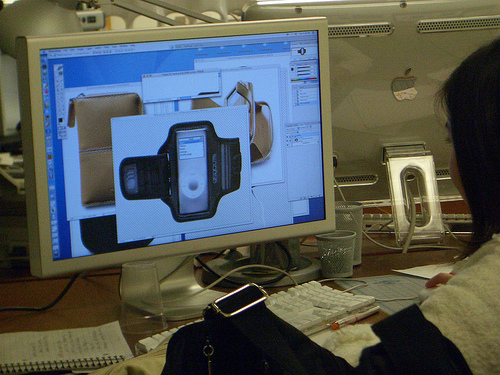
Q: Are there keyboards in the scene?
A: Yes, there is a keyboard.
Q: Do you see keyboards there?
A: Yes, there is a keyboard.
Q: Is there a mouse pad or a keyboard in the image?
A: Yes, there is a keyboard.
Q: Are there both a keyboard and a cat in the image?
A: No, there is a keyboard but no cats.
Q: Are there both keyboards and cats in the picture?
A: No, there is a keyboard but no cats.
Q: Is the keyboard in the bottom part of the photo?
A: Yes, the keyboard is in the bottom of the image.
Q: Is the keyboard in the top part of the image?
A: No, the keyboard is in the bottom of the image.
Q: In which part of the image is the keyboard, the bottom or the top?
A: The keyboard is in the bottom of the image.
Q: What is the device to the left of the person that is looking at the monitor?
A: The device is a keyboard.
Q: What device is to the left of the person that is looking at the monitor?
A: The device is a keyboard.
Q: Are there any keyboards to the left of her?
A: Yes, there is a keyboard to the left of the lady.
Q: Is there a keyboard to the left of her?
A: Yes, there is a keyboard to the left of the lady.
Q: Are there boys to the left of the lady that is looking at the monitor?
A: No, there is a keyboard to the left of the lady.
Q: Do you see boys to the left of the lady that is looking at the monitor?
A: No, there is a keyboard to the left of the lady.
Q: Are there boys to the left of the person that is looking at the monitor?
A: No, there is a keyboard to the left of the lady.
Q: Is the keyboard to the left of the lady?
A: Yes, the keyboard is to the left of the lady.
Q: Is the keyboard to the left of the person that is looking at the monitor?
A: Yes, the keyboard is to the left of the lady.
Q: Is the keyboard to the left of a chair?
A: No, the keyboard is to the left of the lady.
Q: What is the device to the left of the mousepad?
A: The device is a keyboard.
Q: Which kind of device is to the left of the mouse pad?
A: The device is a keyboard.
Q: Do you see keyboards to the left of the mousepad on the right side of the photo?
A: Yes, there is a keyboard to the left of the mousepad.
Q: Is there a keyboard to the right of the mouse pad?
A: No, the keyboard is to the left of the mouse pad.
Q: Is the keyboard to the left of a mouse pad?
A: Yes, the keyboard is to the left of a mouse pad.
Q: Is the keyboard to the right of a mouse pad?
A: No, the keyboard is to the left of a mouse pad.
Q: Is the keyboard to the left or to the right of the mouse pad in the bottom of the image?
A: The keyboard is to the left of the mousepad.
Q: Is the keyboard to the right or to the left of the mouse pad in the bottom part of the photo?
A: The keyboard is to the left of the mousepad.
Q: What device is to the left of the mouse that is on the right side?
A: The device is a keyboard.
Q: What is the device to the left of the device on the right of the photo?
A: The device is a keyboard.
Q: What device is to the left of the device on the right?
A: The device is a keyboard.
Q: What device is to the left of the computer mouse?
A: The device is a keyboard.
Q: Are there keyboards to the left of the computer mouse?
A: Yes, there is a keyboard to the left of the computer mouse.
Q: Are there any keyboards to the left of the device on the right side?
A: Yes, there is a keyboard to the left of the computer mouse.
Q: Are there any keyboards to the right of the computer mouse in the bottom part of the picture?
A: No, the keyboard is to the left of the computer mouse.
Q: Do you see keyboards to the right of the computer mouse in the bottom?
A: No, the keyboard is to the left of the computer mouse.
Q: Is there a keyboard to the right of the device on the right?
A: No, the keyboard is to the left of the computer mouse.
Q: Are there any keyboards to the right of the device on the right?
A: No, the keyboard is to the left of the computer mouse.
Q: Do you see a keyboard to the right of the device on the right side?
A: No, the keyboard is to the left of the computer mouse.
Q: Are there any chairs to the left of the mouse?
A: No, there is a keyboard to the left of the mouse.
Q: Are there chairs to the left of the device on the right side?
A: No, there is a keyboard to the left of the mouse.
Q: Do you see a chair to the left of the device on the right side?
A: No, there is a keyboard to the left of the mouse.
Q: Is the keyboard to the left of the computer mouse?
A: Yes, the keyboard is to the left of the computer mouse.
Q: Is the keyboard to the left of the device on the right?
A: Yes, the keyboard is to the left of the computer mouse.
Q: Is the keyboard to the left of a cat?
A: No, the keyboard is to the left of the computer mouse.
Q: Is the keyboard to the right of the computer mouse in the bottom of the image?
A: No, the keyboard is to the left of the mouse.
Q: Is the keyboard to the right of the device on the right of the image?
A: No, the keyboard is to the left of the mouse.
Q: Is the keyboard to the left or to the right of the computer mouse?
A: The keyboard is to the left of the computer mouse.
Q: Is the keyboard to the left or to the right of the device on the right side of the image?
A: The keyboard is to the left of the computer mouse.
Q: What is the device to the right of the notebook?
A: The device is a keyboard.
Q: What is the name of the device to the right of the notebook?
A: The device is a keyboard.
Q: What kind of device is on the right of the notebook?
A: The device is a keyboard.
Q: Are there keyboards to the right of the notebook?
A: Yes, there is a keyboard to the right of the notebook.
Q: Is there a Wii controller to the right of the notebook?
A: No, there is a keyboard to the right of the notebook.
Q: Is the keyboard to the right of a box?
A: No, the keyboard is to the right of the notebook.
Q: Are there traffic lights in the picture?
A: No, there are no traffic lights.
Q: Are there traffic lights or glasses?
A: No, there are no traffic lights or glasses.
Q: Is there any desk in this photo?
A: Yes, there is a desk.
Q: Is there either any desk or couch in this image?
A: Yes, there is a desk.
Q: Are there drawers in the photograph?
A: No, there are no drawers.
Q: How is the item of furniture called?
A: The piece of furniture is a desk.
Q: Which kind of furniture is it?
A: The piece of furniture is a desk.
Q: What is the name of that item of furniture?
A: This is a desk.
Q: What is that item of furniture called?
A: This is a desk.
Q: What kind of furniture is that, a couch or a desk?
A: This is a desk.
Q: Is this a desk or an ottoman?
A: This is a desk.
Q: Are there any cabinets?
A: No, there are no cabinets.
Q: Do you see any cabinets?
A: No, there are no cabinets.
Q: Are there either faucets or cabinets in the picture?
A: No, there are no cabinets or faucets.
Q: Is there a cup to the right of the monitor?
A: Yes, there are cups to the right of the monitor.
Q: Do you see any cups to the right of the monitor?
A: Yes, there are cups to the right of the monitor.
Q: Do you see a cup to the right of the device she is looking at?
A: Yes, there are cups to the right of the monitor.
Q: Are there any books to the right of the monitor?
A: No, there are cups to the right of the monitor.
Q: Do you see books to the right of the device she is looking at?
A: No, there are cups to the right of the monitor.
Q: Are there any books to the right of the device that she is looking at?
A: No, there are cups to the right of the monitor.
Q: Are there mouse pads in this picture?
A: Yes, there is a mouse pad.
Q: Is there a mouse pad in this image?
A: Yes, there is a mouse pad.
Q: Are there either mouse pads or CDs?
A: Yes, there is a mouse pad.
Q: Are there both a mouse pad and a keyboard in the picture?
A: Yes, there are both a mouse pad and a keyboard.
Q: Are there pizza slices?
A: No, there are no pizza slices.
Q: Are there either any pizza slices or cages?
A: No, there are no pizza slices or cages.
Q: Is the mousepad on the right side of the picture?
A: Yes, the mousepad is on the right of the image.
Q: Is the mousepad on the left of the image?
A: No, the mousepad is on the right of the image.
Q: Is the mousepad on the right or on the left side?
A: The mousepad is on the right of the image.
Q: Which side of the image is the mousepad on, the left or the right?
A: The mousepad is on the right of the image.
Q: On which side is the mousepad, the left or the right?
A: The mousepad is on the right of the image.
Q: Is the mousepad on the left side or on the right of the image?
A: The mousepad is on the right of the image.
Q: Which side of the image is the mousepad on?
A: The mousepad is on the right of the image.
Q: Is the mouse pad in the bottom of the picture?
A: Yes, the mouse pad is in the bottom of the image.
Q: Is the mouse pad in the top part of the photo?
A: No, the mouse pad is in the bottom of the image.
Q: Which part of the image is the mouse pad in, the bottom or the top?
A: The mouse pad is in the bottom of the image.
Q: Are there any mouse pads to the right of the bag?
A: Yes, there is a mouse pad to the right of the bag.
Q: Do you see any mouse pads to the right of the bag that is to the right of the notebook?
A: Yes, there is a mouse pad to the right of the bag.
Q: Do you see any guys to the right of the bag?
A: No, there is a mouse pad to the right of the bag.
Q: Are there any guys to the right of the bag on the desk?
A: No, there is a mouse pad to the right of the bag.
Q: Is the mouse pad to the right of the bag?
A: Yes, the mouse pad is to the right of the bag.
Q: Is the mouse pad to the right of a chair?
A: No, the mouse pad is to the right of the bag.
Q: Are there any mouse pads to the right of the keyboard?
A: Yes, there is a mouse pad to the right of the keyboard.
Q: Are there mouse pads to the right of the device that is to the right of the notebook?
A: Yes, there is a mouse pad to the right of the keyboard.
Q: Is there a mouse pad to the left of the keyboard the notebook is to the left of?
A: No, the mouse pad is to the right of the keyboard.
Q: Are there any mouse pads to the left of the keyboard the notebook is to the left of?
A: No, the mouse pad is to the right of the keyboard.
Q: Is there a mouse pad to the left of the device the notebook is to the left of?
A: No, the mouse pad is to the right of the keyboard.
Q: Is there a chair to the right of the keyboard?
A: No, there is a mouse pad to the right of the keyboard.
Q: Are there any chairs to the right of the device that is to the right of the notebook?
A: No, there is a mouse pad to the right of the keyboard.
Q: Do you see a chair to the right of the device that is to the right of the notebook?
A: No, there is a mouse pad to the right of the keyboard.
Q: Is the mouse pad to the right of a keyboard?
A: Yes, the mouse pad is to the right of a keyboard.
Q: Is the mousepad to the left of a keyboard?
A: No, the mousepad is to the right of a keyboard.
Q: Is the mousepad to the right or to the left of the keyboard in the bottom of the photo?
A: The mousepad is to the right of the keyboard.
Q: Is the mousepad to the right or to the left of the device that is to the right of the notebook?
A: The mousepad is to the right of the keyboard.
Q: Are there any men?
A: No, there are no men.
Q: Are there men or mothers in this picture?
A: No, there are no men or mothers.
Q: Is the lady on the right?
A: Yes, the lady is on the right of the image.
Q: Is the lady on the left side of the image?
A: No, the lady is on the right of the image.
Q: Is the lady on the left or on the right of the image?
A: The lady is on the right of the image.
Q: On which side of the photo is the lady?
A: The lady is on the right of the image.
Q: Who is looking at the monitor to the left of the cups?
A: The lady is looking at the monitor.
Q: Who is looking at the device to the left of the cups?
A: The lady is looking at the monitor.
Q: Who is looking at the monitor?
A: The lady is looking at the monitor.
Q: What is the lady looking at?
A: The lady is looking at the monitor.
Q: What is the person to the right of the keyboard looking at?
A: The lady is looking at the monitor.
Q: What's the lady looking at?
A: The lady is looking at the monitor.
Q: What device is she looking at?
A: The lady is looking at the monitor.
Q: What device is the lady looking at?
A: The lady is looking at the monitor.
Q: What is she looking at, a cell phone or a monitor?
A: The lady is looking at a monitor.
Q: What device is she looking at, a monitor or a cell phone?
A: The lady is looking at a monitor.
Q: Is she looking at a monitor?
A: Yes, the lady is looking at a monitor.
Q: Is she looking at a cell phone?
A: No, the lady is looking at a monitor.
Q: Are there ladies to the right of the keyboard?
A: Yes, there is a lady to the right of the keyboard.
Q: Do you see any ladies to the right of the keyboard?
A: Yes, there is a lady to the right of the keyboard.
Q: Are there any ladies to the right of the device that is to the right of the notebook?
A: Yes, there is a lady to the right of the keyboard.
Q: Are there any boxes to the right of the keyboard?
A: No, there is a lady to the right of the keyboard.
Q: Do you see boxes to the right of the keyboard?
A: No, there is a lady to the right of the keyboard.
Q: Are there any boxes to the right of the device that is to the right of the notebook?
A: No, there is a lady to the right of the keyboard.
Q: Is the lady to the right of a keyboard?
A: Yes, the lady is to the right of a keyboard.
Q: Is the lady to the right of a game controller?
A: No, the lady is to the right of a keyboard.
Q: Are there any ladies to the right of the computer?
A: Yes, there is a lady to the right of the computer.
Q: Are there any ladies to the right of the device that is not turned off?
A: Yes, there is a lady to the right of the computer.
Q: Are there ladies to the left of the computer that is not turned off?
A: No, the lady is to the right of the computer.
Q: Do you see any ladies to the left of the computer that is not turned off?
A: No, the lady is to the right of the computer.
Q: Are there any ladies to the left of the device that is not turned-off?
A: No, the lady is to the right of the computer.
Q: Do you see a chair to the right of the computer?
A: No, there is a lady to the right of the computer.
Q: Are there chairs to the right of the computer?
A: No, there is a lady to the right of the computer.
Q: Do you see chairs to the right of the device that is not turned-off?
A: No, there is a lady to the right of the computer.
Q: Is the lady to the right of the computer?
A: Yes, the lady is to the right of the computer.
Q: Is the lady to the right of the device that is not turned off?
A: Yes, the lady is to the right of the computer.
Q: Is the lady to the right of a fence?
A: No, the lady is to the right of the computer.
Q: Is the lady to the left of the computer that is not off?
A: No, the lady is to the right of the computer.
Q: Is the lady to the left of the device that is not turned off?
A: No, the lady is to the right of the computer.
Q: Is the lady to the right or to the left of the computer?
A: The lady is to the right of the computer.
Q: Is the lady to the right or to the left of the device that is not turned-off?
A: The lady is to the right of the computer.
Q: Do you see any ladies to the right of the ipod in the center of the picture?
A: Yes, there is a lady to the right of the ipod.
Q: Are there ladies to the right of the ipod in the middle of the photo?
A: Yes, there is a lady to the right of the ipod.